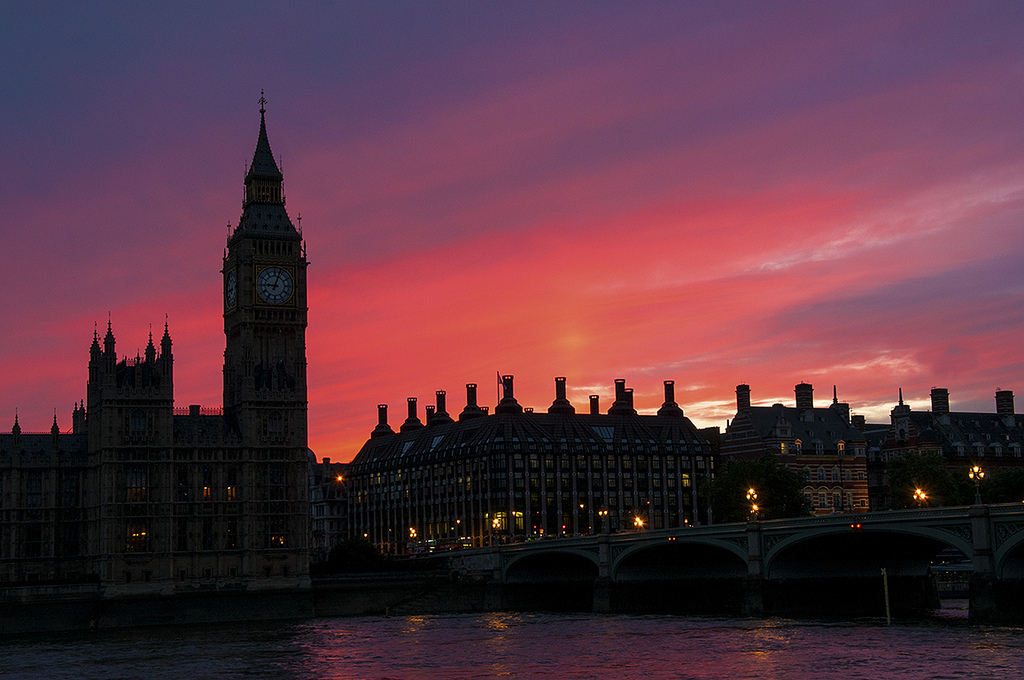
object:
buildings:
[347, 369, 868, 563]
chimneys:
[0, 85, 1024, 680]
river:
[0, 604, 1022, 680]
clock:
[252, 264, 299, 304]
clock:
[221, 262, 300, 317]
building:
[3, 310, 227, 600]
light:
[747, 483, 764, 523]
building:
[217, 89, 312, 461]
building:
[347, 369, 1023, 558]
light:
[126, 527, 148, 551]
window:
[124, 523, 151, 552]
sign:
[337, 526, 1024, 629]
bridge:
[340, 498, 1024, 620]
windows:
[348, 452, 717, 506]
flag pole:
[496, 370, 507, 413]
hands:
[269, 279, 296, 299]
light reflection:
[403, 608, 435, 637]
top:
[257, 87, 270, 141]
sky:
[0, 0, 1024, 464]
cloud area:
[0, 0, 1024, 464]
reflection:
[288, 611, 1024, 680]